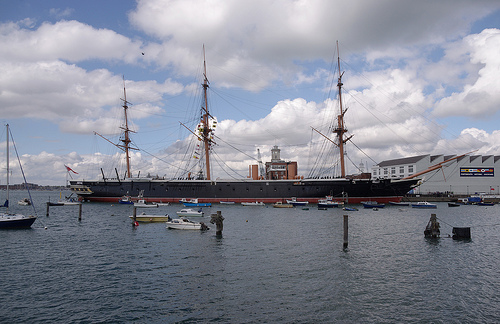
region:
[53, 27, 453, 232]
A Ship is in the water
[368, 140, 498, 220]
A building is in the background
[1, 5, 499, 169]
The sky is bright and cloudy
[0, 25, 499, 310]
Photo was taken in the daytime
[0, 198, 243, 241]
Smaller boats are in the foreground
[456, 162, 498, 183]
Building has a sign on the side of it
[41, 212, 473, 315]
The water is dark blue in color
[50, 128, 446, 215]
Ship is black and red on the bottom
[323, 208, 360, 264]
Pole is sticking out of the water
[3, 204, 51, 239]
Smaller boat is dark blue in color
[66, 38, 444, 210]
large sailboat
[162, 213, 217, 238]
small white sailboat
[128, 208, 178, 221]
white and yellow sailboat in the water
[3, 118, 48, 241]
small sail boat in the water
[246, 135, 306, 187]
large building close to waterway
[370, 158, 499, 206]
large white building on the water front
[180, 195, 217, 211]
small blue boat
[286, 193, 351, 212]
small boats along the side of a large sailboat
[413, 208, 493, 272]
bowie in the water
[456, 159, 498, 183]
advertising banner on side of water front building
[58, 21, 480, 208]
large three mast ship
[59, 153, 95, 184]
flag at the stern of a ship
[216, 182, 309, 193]
starboard windows on a ship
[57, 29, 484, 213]
black and red sailing ship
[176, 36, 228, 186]
main mast of ship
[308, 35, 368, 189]
fore mast of a three mast ship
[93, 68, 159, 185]
mizzen mast of a three mast ship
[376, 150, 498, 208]
large white building at a dock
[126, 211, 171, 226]
small yellow and white motor boat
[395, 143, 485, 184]
bowsprit of a large sailing ship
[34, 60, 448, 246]
Boat in the water.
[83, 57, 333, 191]
Masts on the boat.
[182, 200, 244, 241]
Person in the water.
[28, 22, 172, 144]
clouds in the sky.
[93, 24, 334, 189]
Blue sky with clouds.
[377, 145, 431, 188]
Building behind the water.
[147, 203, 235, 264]
Smaller boats in the water.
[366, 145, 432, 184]
Windows on the building.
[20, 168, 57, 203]
Trees behind the water.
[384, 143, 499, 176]
Roof on the building.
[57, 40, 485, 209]
antique ship in a harbor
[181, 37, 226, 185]
main mast of antique ship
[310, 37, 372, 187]
bow mast on antique ship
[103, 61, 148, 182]
stern mast on antique ship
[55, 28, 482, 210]
antique frigate docked in harbor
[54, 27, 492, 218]
antique sailing vessel painted black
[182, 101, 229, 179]
flags on main mast of antique ship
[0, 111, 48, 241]
sailboat docked in harbor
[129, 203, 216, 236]
three boats in a harbor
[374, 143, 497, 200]
waterfront building in a harbor